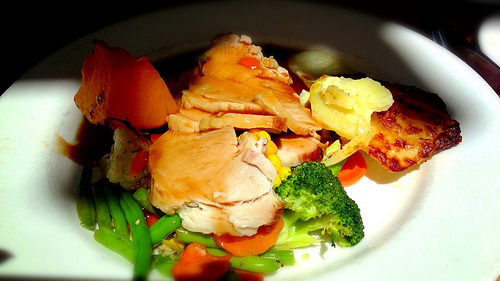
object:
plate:
[4, 2, 498, 279]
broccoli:
[265, 156, 377, 256]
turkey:
[133, 109, 299, 241]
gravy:
[78, 135, 105, 154]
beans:
[107, 186, 158, 279]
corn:
[248, 131, 293, 179]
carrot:
[46, 35, 178, 132]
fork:
[419, 20, 456, 53]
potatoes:
[349, 71, 470, 177]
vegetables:
[49, 43, 178, 275]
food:
[32, 26, 475, 281]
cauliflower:
[95, 123, 157, 187]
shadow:
[21, 5, 408, 69]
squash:
[285, 39, 342, 80]